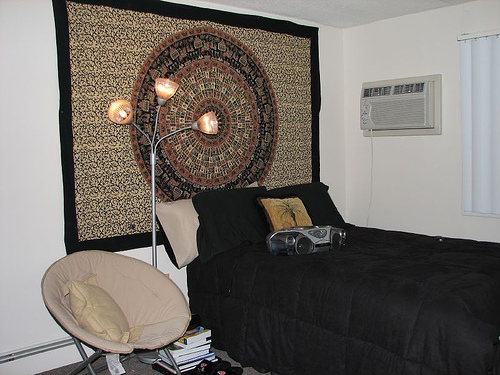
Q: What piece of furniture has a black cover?
A: Bed.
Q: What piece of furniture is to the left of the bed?
A: Chair.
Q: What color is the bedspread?
A: Black.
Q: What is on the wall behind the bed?
A: A tapestry.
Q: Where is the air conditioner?
A: On the wall to the right of the bed.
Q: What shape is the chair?
A: Round.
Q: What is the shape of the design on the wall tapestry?
A: Circle.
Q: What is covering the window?
A: Vertical blinds.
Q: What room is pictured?
A: Bedroom.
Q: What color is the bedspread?
A: Black.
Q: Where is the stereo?
A: On the bed.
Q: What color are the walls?
A: White.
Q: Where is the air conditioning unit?
A: In the wall.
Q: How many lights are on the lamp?
A: 3.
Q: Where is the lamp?
A: Next to the bed.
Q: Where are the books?
A: On the floor.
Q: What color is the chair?
A: Beige.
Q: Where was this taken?
A: Bedroom.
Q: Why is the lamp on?
A: Dark.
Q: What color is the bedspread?
A: Black.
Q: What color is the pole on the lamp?
A: Silver.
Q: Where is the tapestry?
A: On the wall.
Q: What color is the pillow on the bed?
A: Tan.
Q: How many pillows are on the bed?
A: 5.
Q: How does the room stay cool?
A: Wall unit air-conditioner.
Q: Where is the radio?
A: On bed.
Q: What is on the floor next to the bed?
A: Books.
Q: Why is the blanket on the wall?
A: Decoration.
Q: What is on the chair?
A: Pillow.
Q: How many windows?
A: One.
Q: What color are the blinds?
A: White.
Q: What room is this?
A: Bedroom.